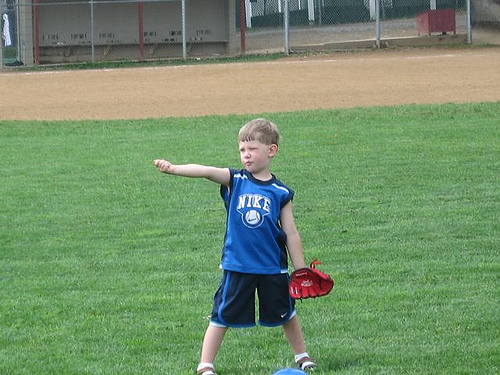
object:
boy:
[152, 118, 333, 374]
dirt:
[0, 47, 499, 121]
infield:
[0, 101, 499, 373]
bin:
[414, 9, 455, 38]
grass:
[1, 98, 499, 374]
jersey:
[218, 167, 295, 275]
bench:
[38, 29, 229, 67]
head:
[236, 119, 280, 172]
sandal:
[294, 351, 320, 375]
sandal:
[195, 362, 218, 374]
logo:
[234, 193, 272, 231]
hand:
[287, 268, 333, 299]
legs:
[200, 281, 250, 358]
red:
[300, 287, 317, 294]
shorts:
[207, 270, 296, 328]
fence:
[0, 0, 499, 66]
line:
[0, 52, 499, 78]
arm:
[172, 163, 231, 188]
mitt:
[287, 256, 333, 303]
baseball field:
[0, 47, 498, 374]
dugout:
[16, 1, 245, 67]